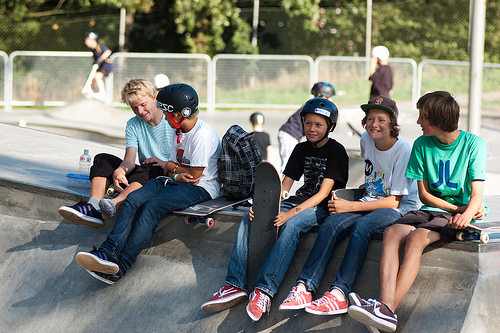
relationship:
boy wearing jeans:
[278, 96, 422, 314] [224, 203, 326, 296]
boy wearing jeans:
[75, 84, 226, 283] [99, 176, 214, 264]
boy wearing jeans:
[278, 96, 422, 314] [295, 207, 405, 296]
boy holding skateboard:
[278, 96, 422, 314] [247, 161, 282, 303]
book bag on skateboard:
[219, 125, 260, 196] [175, 197, 254, 225]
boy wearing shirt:
[350, 92, 488, 330] [408, 129, 488, 218]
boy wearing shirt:
[278, 96, 422, 314] [282, 138, 348, 214]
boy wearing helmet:
[278, 96, 422, 314] [300, 99, 338, 146]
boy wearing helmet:
[75, 84, 226, 283] [158, 83, 199, 119]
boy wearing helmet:
[278, 96, 422, 314] [311, 80, 335, 100]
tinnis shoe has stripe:
[76, 251, 119, 272] [94, 250, 102, 260]